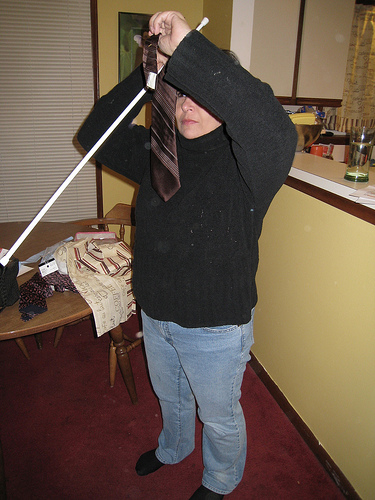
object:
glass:
[345, 126, 373, 182]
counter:
[254, 135, 374, 498]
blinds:
[0, 109, 94, 114]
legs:
[179, 315, 255, 500]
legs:
[130, 309, 193, 476]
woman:
[74, 11, 302, 498]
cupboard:
[252, 2, 351, 110]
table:
[0, 220, 140, 404]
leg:
[109, 322, 138, 403]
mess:
[15, 227, 136, 337]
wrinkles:
[204, 419, 214, 428]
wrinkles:
[160, 441, 163, 448]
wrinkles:
[214, 470, 226, 476]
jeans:
[137, 305, 251, 491]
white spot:
[319, 441, 321, 444]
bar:
[267, 149, 370, 208]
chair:
[52, 200, 166, 408]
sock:
[189, 483, 225, 499]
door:
[2, 0, 101, 227]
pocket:
[198, 315, 241, 338]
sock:
[134, 447, 164, 474]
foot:
[133, 445, 181, 477]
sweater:
[74, 30, 300, 331]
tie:
[132, 27, 180, 199]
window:
[0, 1, 102, 223]